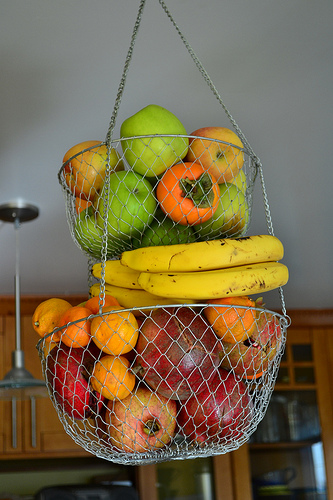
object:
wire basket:
[36, 303, 288, 468]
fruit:
[90, 354, 136, 398]